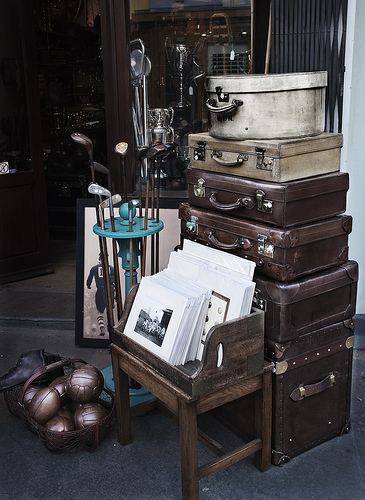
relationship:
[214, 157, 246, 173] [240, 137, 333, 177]
buckle on trunk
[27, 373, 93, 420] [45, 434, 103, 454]
balls in basket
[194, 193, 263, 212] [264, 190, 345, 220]
handle on suitcase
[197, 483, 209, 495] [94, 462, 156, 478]
spot on carpet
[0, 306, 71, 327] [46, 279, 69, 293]
step on floor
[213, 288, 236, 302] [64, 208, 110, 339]
frame on picture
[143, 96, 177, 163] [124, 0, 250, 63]
trophy in window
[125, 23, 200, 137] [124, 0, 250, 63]
merchandise in window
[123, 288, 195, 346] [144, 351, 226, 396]
pictures in crate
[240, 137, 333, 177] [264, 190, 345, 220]
trunk under suitcase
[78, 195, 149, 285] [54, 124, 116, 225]
holder for golf club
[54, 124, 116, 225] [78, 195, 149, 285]
golf club in holder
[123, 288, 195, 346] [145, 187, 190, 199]
pictures on table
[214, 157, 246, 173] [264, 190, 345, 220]
buckle on suitcase